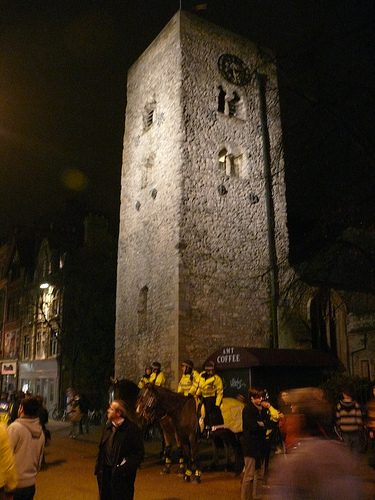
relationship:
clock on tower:
[215, 50, 252, 89] [107, 6, 293, 389]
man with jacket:
[92, 399, 141, 498] [92, 418, 145, 478]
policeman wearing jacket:
[188, 361, 225, 436] [189, 373, 223, 405]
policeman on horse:
[188, 361, 225, 436] [138, 381, 244, 483]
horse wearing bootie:
[138, 381, 244, 483] [193, 468, 203, 480]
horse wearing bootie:
[138, 381, 244, 483] [183, 468, 195, 478]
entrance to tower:
[308, 285, 352, 376] [107, 6, 293, 389]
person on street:
[7, 392, 49, 498] [4, 442, 240, 498]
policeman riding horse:
[177, 356, 199, 395] [138, 381, 244, 483]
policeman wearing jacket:
[146, 358, 167, 387] [146, 370, 167, 386]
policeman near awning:
[188, 361, 225, 436] [199, 342, 349, 375]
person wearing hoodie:
[331, 383, 365, 447] [332, 398, 364, 431]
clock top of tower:
[215, 50, 252, 89] [107, 6, 293, 389]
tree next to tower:
[255, 221, 372, 344] [107, 6, 293, 389]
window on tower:
[211, 139, 232, 176] [107, 6, 293, 389]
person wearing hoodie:
[7, 392, 49, 498] [6, 421, 46, 487]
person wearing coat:
[238, 385, 270, 498] [238, 402, 271, 458]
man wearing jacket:
[92, 399, 141, 498] [92, 418, 145, 478]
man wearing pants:
[92, 399, 141, 498] [94, 469, 135, 498]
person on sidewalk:
[61, 396, 84, 436] [46, 418, 167, 456]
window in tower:
[229, 145, 246, 182] [107, 6, 293, 389]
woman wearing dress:
[275, 400, 309, 455] [275, 416, 304, 453]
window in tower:
[135, 283, 149, 335] [107, 6, 293, 389]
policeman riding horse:
[188, 361, 225, 436] [138, 381, 244, 483]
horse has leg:
[138, 381, 244, 483] [187, 428, 203, 482]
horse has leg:
[138, 381, 244, 483] [179, 430, 193, 481]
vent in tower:
[142, 104, 156, 129] [107, 6, 293, 389]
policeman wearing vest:
[139, 363, 153, 391] [138, 377, 150, 390]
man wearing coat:
[238, 385, 270, 498] [238, 402, 271, 458]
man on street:
[238, 385, 270, 498] [4, 442, 240, 498]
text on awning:
[214, 351, 243, 365] [199, 342, 349, 375]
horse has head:
[138, 381, 244, 483] [139, 381, 168, 430]